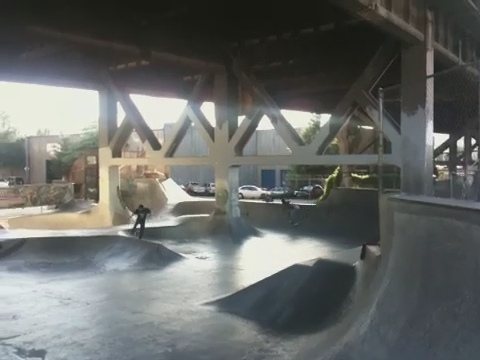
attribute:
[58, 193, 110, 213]
grass — brown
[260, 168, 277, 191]
door — blue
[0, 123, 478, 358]
park — sunny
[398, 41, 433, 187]
beam — white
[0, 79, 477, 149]
sky — sunny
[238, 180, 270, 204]
car — white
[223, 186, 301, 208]
car — white, parked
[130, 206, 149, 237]
clothing — dark